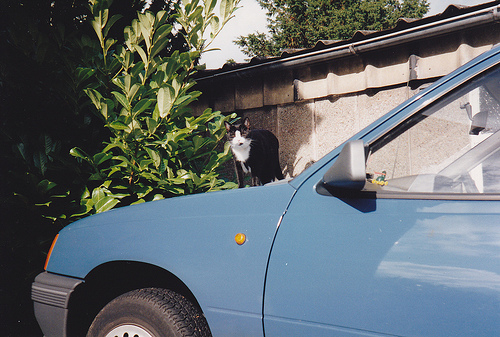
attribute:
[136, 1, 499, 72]
sky — bright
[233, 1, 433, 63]
tree — in background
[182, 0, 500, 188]
structure — cement, concrete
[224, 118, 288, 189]
cat — black, standing, white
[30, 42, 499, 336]
car — blue, parked